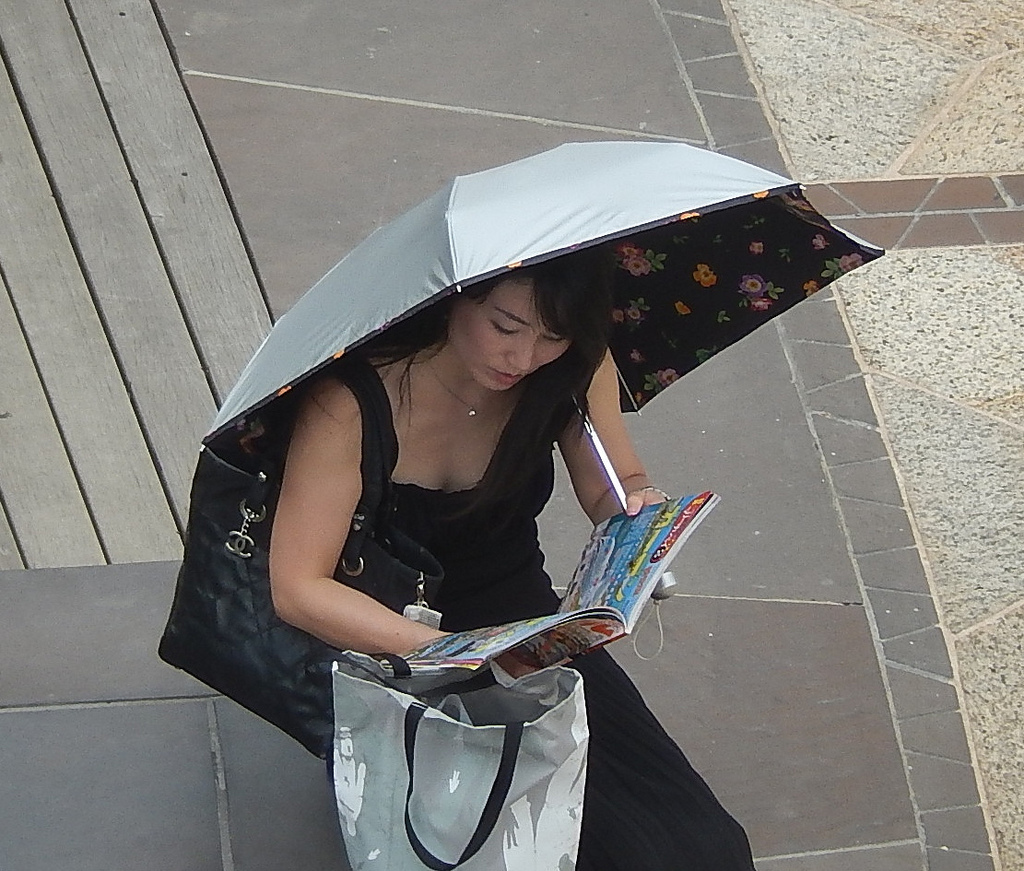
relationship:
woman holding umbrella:
[265, 251, 745, 871] [157, 72, 909, 500]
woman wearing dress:
[265, 251, 745, 871] [274, 394, 815, 820]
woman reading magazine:
[265, 251, 745, 871] [196, 489, 981, 740]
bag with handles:
[347, 640, 670, 850] [384, 685, 523, 850]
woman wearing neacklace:
[265, 251, 745, 871] [417, 370, 534, 433]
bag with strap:
[329, 649, 584, 870] [402, 668, 545, 856]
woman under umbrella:
[265, 251, 745, 871] [175, 132, 901, 433]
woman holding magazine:
[190, 340, 986, 863] [384, 523, 773, 753]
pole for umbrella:
[576, 404, 689, 603] [172, 111, 913, 440]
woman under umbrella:
[265, 251, 745, 871] [147, 117, 917, 327]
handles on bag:
[402, 693, 522, 870] [328, 618, 687, 845]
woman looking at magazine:
[265, 251, 745, 871] [395, 485, 724, 682]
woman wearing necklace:
[265, 251, 745, 871] [425, 353, 501, 421]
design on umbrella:
[606, 189, 890, 412] [194, 122, 899, 622]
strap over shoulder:
[341, 361, 413, 495] [295, 383, 362, 470]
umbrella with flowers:
[194, 122, 899, 622] [600, 214, 778, 340]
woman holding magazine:
[265, 251, 745, 871] [395, 485, 724, 682]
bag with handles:
[329, 649, 584, 870] [369, 655, 532, 865]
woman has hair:
[265, 251, 745, 871] [535, 251, 622, 466]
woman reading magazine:
[265, 251, 745, 871] [386, 489, 730, 691]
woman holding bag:
[265, 251, 745, 871] [153, 363, 456, 787]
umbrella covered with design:
[194, 122, 899, 622] [607, 185, 883, 410]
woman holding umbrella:
[265, 251, 745, 871] [194, 122, 899, 622]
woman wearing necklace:
[265, 251, 745, 871] [401, 361, 499, 428]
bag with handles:
[329, 649, 584, 870] [362, 642, 535, 867]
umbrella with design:
[194, 122, 899, 622] [607, 185, 883, 410]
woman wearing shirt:
[265, 251, 745, 871] [351, 364, 566, 635]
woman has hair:
[265, 251, 745, 871] [520, 249, 620, 451]